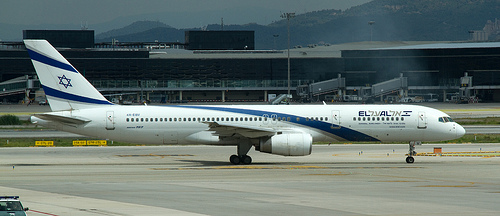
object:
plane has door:
[416, 112, 427, 130]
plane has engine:
[255, 127, 313, 157]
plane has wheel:
[405, 155, 414, 164]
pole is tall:
[283, 14, 294, 104]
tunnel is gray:
[306, 77, 344, 98]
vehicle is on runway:
[0, 195, 33, 216]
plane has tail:
[21, 39, 112, 111]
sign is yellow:
[34, 140, 54, 146]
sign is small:
[70, 141, 88, 146]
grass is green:
[449, 116, 497, 127]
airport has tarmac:
[0, 99, 499, 216]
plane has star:
[55, 74, 75, 88]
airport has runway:
[0, 142, 499, 216]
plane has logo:
[357, 110, 412, 118]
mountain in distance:
[94, 0, 498, 51]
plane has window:
[124, 118, 129, 123]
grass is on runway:
[308, 132, 500, 146]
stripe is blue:
[25, 50, 78, 74]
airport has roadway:
[0, 125, 498, 138]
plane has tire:
[242, 155, 251, 165]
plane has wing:
[199, 119, 279, 141]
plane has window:
[129, 118, 135, 122]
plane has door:
[330, 109, 341, 130]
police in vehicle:
[0, 195, 31, 216]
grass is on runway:
[0, 114, 28, 125]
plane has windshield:
[437, 117, 443, 123]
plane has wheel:
[226, 153, 241, 164]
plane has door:
[103, 110, 116, 130]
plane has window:
[162, 118, 168, 122]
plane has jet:
[251, 127, 313, 156]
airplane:
[20, 39, 465, 166]